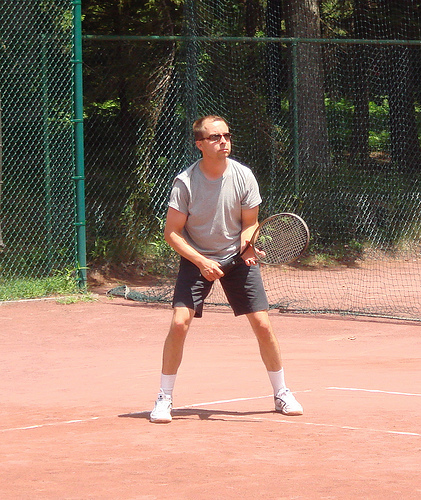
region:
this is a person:
[143, 108, 317, 436]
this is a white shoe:
[131, 357, 217, 450]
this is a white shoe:
[244, 352, 318, 441]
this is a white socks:
[152, 353, 189, 411]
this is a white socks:
[258, 353, 293, 396]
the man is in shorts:
[156, 224, 272, 327]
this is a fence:
[0, 0, 416, 311]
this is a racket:
[204, 209, 320, 276]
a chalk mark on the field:
[23, 391, 106, 432]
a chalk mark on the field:
[317, 415, 373, 461]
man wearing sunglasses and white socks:
[148, 114, 306, 424]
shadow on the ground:
[174, 402, 269, 421]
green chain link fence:
[8, 48, 51, 272]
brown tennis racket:
[207, 211, 308, 272]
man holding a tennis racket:
[156, 113, 308, 416]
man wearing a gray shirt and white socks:
[150, 113, 306, 423]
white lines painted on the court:
[302, 380, 416, 440]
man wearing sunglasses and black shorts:
[141, 113, 304, 418]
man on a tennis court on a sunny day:
[150, 112, 317, 437]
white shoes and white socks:
[149, 366, 301, 420]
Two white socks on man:
[146, 369, 294, 399]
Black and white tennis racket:
[193, 204, 324, 288]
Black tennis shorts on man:
[163, 238, 273, 336]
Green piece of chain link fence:
[0, 2, 112, 306]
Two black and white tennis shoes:
[130, 385, 316, 436]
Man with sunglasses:
[178, 110, 237, 168]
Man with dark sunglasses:
[197, 128, 234, 146]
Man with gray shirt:
[154, 140, 268, 284]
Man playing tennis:
[148, 108, 313, 435]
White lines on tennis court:
[1, 379, 419, 497]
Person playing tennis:
[145, 115, 310, 422]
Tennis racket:
[214, 212, 309, 274]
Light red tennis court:
[2, 291, 418, 496]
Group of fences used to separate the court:
[1, 3, 419, 326]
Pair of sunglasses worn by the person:
[193, 133, 233, 142]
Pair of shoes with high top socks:
[150, 372, 305, 418]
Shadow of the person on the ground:
[116, 403, 292, 425]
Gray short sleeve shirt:
[164, 158, 262, 263]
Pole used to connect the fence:
[68, 0, 89, 301]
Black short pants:
[173, 258, 270, 318]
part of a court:
[397, 346, 401, 355]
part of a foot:
[285, 390, 309, 418]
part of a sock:
[275, 380, 288, 402]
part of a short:
[252, 296, 255, 302]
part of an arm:
[215, 261, 218, 267]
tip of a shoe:
[290, 406, 299, 433]